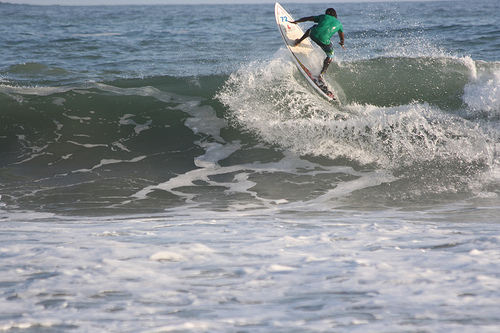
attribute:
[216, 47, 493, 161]
wake — white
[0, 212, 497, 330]
water — white, choppy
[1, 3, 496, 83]
water — blue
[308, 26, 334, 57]
shorts — black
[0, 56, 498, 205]
wave — splashy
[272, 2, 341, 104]
board — red, white, big